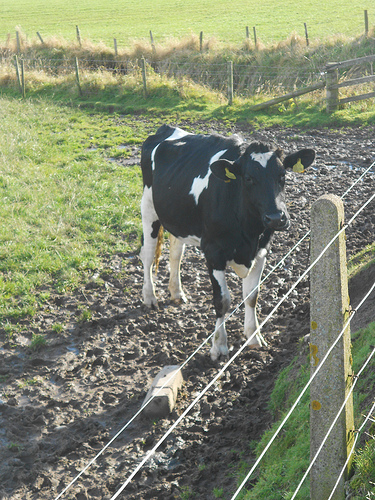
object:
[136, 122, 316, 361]
cow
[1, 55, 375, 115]
fence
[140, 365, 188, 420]
plank of wood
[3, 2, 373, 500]
ground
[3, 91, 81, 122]
grass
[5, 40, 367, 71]
hay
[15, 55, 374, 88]
wires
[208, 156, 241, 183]
ear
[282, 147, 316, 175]
ear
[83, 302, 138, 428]
mud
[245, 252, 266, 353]
leg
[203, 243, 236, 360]
leg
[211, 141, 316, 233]
head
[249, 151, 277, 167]
spot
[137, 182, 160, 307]
back leg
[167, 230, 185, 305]
back leg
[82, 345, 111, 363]
step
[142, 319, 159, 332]
step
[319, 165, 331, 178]
step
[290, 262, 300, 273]
step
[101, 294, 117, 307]
step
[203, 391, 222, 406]
step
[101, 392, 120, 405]
step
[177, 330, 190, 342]
step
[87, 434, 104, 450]
step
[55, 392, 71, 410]
step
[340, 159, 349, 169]
step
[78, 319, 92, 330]
step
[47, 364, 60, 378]
step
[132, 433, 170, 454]
step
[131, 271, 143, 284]
step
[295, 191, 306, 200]
step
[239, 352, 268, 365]
step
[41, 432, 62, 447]
step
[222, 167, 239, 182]
tag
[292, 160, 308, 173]
tag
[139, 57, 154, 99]
fence post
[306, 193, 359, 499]
fence post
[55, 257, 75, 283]
grass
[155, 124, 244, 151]
back bone